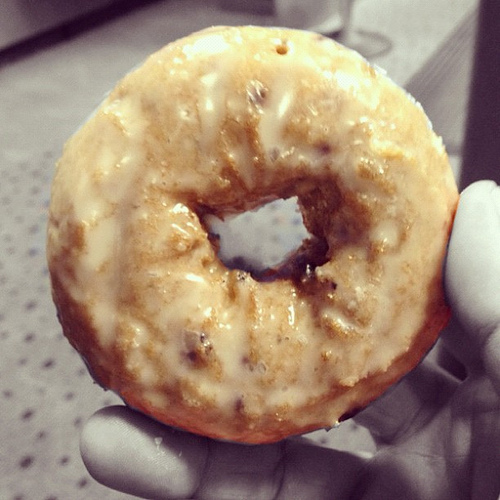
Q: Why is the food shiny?
A: Frosting.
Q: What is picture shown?
A: Donut.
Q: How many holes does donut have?
A: One.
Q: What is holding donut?
A: Hand.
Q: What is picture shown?
A: Donut.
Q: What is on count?
A: Icing.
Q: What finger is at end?
A: Pinky.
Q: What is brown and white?
A: Donut.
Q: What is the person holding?
A: A doughnut.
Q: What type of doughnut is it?
A: Glazed.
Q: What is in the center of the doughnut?
A: Hole.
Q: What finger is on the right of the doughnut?
A: Thumb.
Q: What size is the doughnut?
A: Large.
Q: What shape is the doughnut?
A: Large.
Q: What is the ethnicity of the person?
A: White.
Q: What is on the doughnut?
A: Icing.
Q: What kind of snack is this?
A: Doughnut.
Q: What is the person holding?
A: Donut.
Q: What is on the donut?
A: Glaze.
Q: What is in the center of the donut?
A: Hole.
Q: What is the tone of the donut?
A: Brown.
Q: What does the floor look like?
A: Speckled.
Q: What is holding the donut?
A: Hand.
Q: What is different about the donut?
A: Color.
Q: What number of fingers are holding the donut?
A: 3.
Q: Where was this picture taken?
A: Bakery.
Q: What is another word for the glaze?
A: Icing.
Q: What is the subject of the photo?
A: Donut.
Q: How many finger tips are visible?
A: Two.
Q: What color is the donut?
A: Brown.